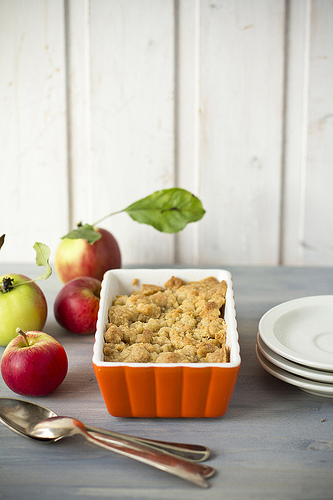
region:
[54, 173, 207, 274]
apple with long stem and large leaves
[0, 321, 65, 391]
red apple with short stem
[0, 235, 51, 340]
apple with curled stem and partial leaf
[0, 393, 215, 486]
spoon resting inside spoon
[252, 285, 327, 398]
short stack of white plates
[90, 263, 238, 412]
orange and white rectangular container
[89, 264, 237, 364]
scalloped edge along rim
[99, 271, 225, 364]
baked browned crust in dish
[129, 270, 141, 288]
crumb stuck to side of dish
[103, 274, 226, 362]
crumbly and rounded surface of crust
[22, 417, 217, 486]
a silver spoon utensil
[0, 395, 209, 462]
a silver spoon utensil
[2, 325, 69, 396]
a red green apple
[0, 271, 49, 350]
a green red apple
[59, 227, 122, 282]
a green red apple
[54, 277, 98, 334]
a red green apple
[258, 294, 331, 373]
a small white plate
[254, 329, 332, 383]
a small white plate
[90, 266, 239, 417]
a small orange dish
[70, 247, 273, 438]
fresh apple crisp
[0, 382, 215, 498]
spoons laying on counter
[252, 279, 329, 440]
Three saucers sitting on table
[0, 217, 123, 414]
4 apples on table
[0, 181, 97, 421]
fresh picked apples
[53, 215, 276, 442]
apple crisp in orange dish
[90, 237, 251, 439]
apple crumb dessert on table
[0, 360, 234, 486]
silver spoons on table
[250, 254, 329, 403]
white glass plates on table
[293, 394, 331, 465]
crumbs on wood table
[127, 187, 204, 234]
a leaf on an applle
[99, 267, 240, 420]
food in an orange pan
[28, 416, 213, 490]
a silver spoon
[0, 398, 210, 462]
a silver spoon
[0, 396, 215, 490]
two silver spoons on a table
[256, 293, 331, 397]
a stack of white plates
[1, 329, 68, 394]
a red and yellow apple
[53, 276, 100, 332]
a bright red apple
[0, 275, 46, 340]
a yellow and red apple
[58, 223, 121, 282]
a yellow and red apple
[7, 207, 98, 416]
Fruit in the shot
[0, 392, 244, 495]
Spoon lying on the ground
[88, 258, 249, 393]
Oatmeal in the bowl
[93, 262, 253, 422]
The bowl is white and orange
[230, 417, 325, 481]
The table is grey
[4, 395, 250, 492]
Two spoons on top of each other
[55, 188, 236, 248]
Leaves sticking out of the fruit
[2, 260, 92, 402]
The fruit is red and green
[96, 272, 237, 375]
Oatmeal is cold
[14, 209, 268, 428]
Breakfast is the dish